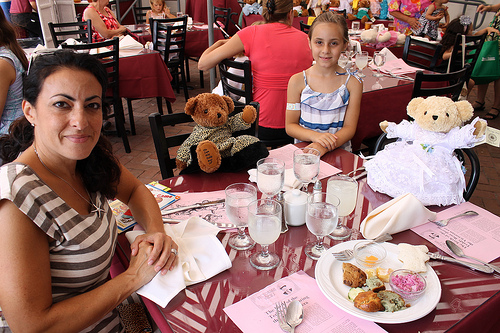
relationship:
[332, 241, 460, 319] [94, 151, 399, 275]
food sitting on table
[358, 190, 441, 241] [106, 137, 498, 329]
napkin on table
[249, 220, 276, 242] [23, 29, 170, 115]
water sitting on top of table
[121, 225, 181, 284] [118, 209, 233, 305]
hands on top of napkins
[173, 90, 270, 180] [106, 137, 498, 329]
bear sitting at table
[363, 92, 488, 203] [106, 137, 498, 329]
bear sitting at table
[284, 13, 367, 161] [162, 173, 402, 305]
kid standing at table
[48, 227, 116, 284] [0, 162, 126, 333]
stripe on on shirt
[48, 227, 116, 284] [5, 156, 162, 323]
stripe on shirt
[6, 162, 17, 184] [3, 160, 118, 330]
brown stripe on shirt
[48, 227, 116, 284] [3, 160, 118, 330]
stripe on shirt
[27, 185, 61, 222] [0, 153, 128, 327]
brown stripe on shirt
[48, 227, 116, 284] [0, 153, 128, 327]
stripe on shirt